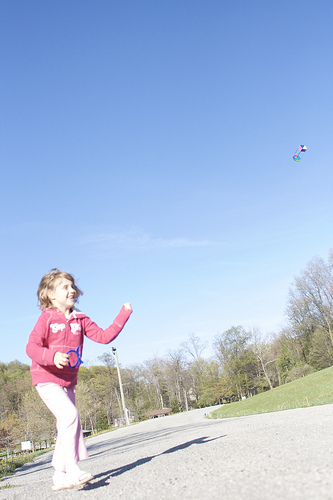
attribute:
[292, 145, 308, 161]
kite — multicolored, flying, colorful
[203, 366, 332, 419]
grass — green, trimmed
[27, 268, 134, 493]
girl — young, blonde, smiling, happy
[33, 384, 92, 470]
pants — pink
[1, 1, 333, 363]
sky — blue, clear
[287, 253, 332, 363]
tree — bare, tall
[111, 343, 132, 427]
lamppost — tall, gray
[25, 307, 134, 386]
jacket — pink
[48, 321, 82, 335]
letters — white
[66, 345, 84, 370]
handle — blue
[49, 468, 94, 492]
shoes — white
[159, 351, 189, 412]
tree — bare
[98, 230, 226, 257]
cloud — white